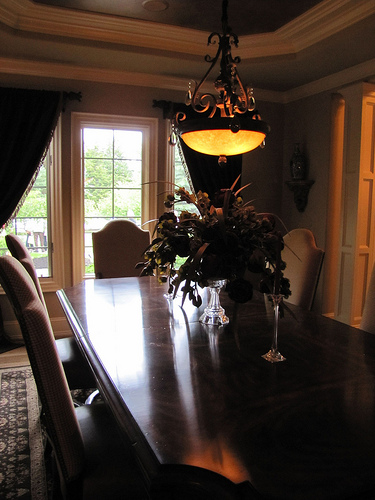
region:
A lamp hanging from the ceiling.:
[162, 6, 273, 172]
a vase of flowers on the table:
[139, 177, 282, 338]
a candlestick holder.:
[263, 211, 289, 369]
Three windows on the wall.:
[10, 103, 221, 306]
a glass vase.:
[200, 275, 232, 337]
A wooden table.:
[57, 255, 368, 498]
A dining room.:
[5, 144, 371, 497]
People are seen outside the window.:
[22, 211, 48, 254]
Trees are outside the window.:
[23, 143, 199, 257]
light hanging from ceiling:
[175, 14, 268, 152]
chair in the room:
[74, 215, 159, 274]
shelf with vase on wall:
[282, 125, 320, 217]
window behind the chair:
[1, 129, 54, 274]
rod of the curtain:
[9, 82, 82, 100]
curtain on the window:
[2, 89, 52, 236]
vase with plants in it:
[259, 282, 289, 362]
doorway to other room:
[355, 89, 373, 326]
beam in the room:
[312, 89, 349, 309]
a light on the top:
[164, 97, 303, 174]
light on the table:
[175, 430, 251, 486]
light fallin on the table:
[155, 424, 260, 490]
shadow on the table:
[144, 372, 196, 434]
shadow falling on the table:
[137, 384, 221, 453]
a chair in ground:
[59, 190, 183, 281]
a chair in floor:
[81, 205, 186, 284]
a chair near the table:
[89, 206, 187, 290]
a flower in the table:
[163, 176, 333, 341]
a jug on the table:
[169, 189, 274, 321]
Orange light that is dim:
[127, 71, 270, 188]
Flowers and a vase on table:
[141, 180, 284, 326]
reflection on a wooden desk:
[58, 258, 174, 393]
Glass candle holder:
[243, 275, 309, 368]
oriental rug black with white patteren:
[0, 366, 60, 482]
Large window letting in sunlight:
[69, 111, 163, 229]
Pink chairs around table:
[0, 235, 104, 451]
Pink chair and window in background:
[77, 211, 171, 286]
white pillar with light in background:
[313, 70, 371, 350]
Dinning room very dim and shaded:
[0, 47, 335, 444]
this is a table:
[115, 305, 210, 450]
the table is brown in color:
[117, 339, 183, 422]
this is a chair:
[15, 257, 81, 462]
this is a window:
[86, 128, 141, 200]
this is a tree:
[156, 183, 253, 281]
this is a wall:
[285, 109, 328, 141]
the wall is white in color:
[280, 89, 331, 121]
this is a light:
[176, 110, 278, 174]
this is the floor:
[2, 375, 46, 444]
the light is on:
[188, 124, 272, 173]